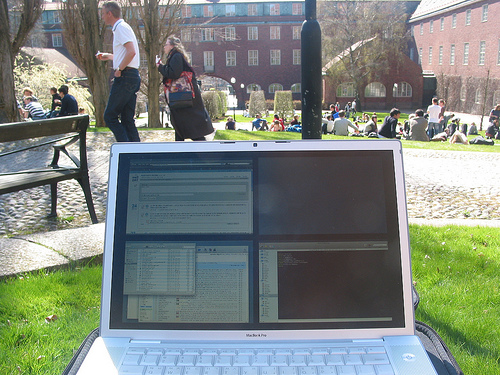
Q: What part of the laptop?
A: Keyboard.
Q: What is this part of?
A: Bench.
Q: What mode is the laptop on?
A: Turned on.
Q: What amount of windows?
A: Four.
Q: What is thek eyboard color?
A: White.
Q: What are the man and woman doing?
A: Walking.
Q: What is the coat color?
A: Black.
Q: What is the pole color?
A: Black.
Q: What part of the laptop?
A: Screen.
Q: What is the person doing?
A: Standing.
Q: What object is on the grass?
A: Laptop.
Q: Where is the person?
A: Standing.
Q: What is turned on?
A: Laptop computer.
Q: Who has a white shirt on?
A: A man.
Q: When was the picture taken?
A: Daytime.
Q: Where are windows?
A: On a building.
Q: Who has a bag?
A: Woman in black.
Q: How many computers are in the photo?
A: One.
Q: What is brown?
A: A building.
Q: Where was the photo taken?
A: In the park.